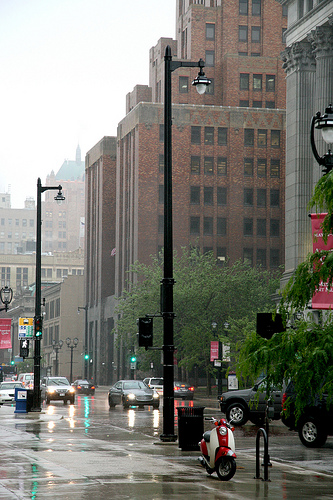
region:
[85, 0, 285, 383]
a tall brick building with several levels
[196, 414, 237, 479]
red and white parked motorbike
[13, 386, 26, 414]
a dark blue dispenser of reading material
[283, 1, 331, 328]
partially visible grey building with massive pillars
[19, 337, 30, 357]
a pedestrian crossing signal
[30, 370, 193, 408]
vehicles with their headlights on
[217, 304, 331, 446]
tree branches partially obscuring view of two vehicles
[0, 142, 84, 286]
buildings in distance appear misty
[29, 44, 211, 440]
two tall black posts suspend street lamps high above ground level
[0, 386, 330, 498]
ground and sidewalk appear wet with rain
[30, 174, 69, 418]
Street light on a very tall pole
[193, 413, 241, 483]
Scooter parked on the street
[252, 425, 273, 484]
Dark black painted metal barrier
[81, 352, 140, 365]
Pair of street lights showing blue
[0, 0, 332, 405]
Array of buildings on the street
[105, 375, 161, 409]
Car with headlights turned on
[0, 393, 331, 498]
Reflective ground of the street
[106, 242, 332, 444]
Vegetation on the street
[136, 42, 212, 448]
Tall street lamp with a traffic light mounted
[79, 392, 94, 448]
Green reflection of light on the ground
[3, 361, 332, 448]
cars on the road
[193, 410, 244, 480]
white and red scooter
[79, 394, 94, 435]
green light reflected on the street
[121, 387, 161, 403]
headlights are on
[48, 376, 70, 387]
two black windshield wipers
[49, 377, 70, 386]
windshield wipers are on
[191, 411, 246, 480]
scooter parked on the sidewalk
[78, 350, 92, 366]
traffic light shining green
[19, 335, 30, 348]
light signaling that it is okay for pedestrians to cross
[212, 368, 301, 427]
SUV that is turning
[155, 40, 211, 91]
light on the pole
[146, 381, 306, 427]
street for vehicles to travel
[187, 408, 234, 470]
motorized bike on walk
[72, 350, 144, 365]
traffic lights that are green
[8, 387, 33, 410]
dispenser for periodicals and books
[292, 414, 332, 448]
tire on the vehicle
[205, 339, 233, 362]
banners on the pole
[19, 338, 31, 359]
pedestrian traffic light for street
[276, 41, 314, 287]
column on the building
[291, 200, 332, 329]
banner hanging from post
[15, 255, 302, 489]
city street on a rainy day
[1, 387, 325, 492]
rain creating a reflective and wet sidewalk and street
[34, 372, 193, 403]
cars with their headlights and rear lights on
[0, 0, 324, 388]
grey stone and brick buildings on one side of street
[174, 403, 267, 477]
garbage can, motorscooter and bicycle rack near curb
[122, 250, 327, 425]
round and long-limbed trees in front of buildings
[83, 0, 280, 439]
tall lamppost in front of building with many levels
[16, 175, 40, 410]
black lamppost with traffic signals showing green circle and white walker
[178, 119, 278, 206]
dark and lighted windows of office building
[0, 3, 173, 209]
bright light over skyline